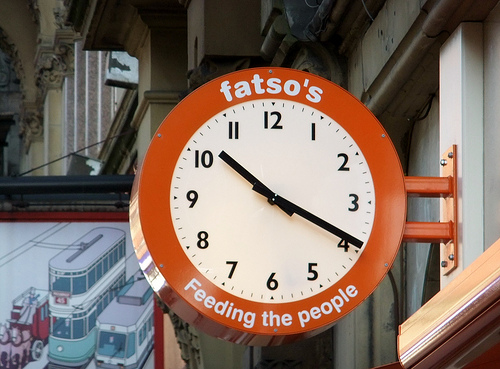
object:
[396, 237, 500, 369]
ledge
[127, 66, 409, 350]
clock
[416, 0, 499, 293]
wall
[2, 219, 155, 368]
transportation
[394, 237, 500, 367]
side trim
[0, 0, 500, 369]
building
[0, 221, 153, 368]
picture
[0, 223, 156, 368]
automobile transportation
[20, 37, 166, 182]
columns